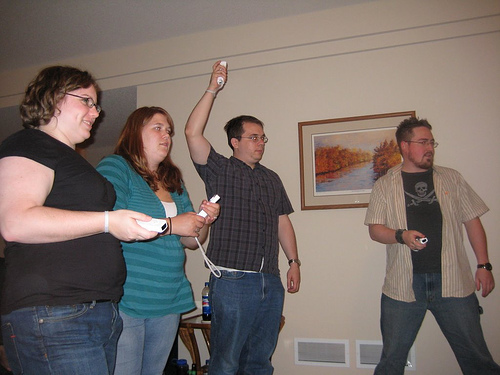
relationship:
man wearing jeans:
[182, 60, 299, 370] [202, 270, 284, 375]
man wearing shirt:
[362, 116, 499, 375] [394, 173, 447, 271]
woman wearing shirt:
[93, 93, 227, 374] [154, 186, 191, 226]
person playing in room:
[0, 64, 160, 371] [1, 1, 482, 372]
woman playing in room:
[93, 104, 220, 374] [1, 1, 482, 372]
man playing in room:
[182, 60, 304, 375] [1, 1, 482, 372]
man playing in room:
[362, 116, 499, 375] [1, 1, 482, 372]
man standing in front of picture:
[362, 116, 498, 373] [295, 106, 420, 211]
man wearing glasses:
[362, 116, 499, 375] [418, 137, 433, 154]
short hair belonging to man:
[386, 112, 446, 141] [362, 95, 490, 363]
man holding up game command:
[182, 60, 299, 370] [214, 60, 228, 90]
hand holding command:
[168, 210, 205, 235] [198, 193, 220, 217]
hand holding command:
[198, 200, 223, 223] [198, 193, 220, 217]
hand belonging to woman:
[168, 210, 205, 235] [91, 106, 218, 373]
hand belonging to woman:
[198, 200, 223, 223] [91, 106, 218, 373]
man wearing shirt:
[182, 60, 299, 370] [201, 145, 293, 277]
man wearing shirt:
[362, 116, 498, 373] [362, 160, 488, 306]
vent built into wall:
[290, 337, 350, 367] [2, 2, 484, 370]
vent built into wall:
[354, 339, 415, 369] [2, 2, 484, 370]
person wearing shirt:
[0, 64, 160, 371] [1, 126, 132, 307]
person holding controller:
[0, 64, 160, 371] [120, 204, 174, 235]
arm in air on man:
[181, 55, 221, 213] [180, 45, 311, 373]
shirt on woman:
[92, 151, 208, 315] [98, 91, 219, 373]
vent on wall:
[293, 337, 350, 367] [178, 27, 498, 374]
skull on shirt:
[402, 182, 437, 211] [396, 166, 443, 271]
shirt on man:
[396, 166, 443, 271] [362, 116, 498, 373]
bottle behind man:
[195, 273, 213, 319] [180, 45, 311, 373]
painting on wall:
[295, 105, 413, 213] [20, 43, 497, 358]